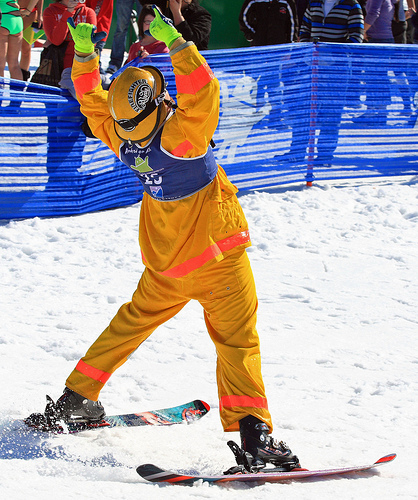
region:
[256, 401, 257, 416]
part of a skate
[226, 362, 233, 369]
back of a leg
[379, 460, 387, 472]
part of a skate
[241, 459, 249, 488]
edge of a skate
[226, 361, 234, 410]
part of a trouser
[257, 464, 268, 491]
edge of a board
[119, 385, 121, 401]
part of a board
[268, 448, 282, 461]
part of a skate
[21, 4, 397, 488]
person standing on skis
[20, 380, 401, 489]
pair of skis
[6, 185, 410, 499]
snow covered hill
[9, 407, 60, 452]
snow splash in air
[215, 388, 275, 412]
orange stripes on yellow outfit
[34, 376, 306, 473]
black snow shoes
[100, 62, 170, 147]
yellow helmet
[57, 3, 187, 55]
neon green gloves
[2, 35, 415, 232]
blue fabric fence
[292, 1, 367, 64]
striped sweater with zipper in front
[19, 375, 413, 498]
a pair of skis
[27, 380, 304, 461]
his boots are black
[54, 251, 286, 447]
his pants are yellow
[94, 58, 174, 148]
his helmet is yellow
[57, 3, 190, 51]
his gloves are neon green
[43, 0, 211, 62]
the gloves are green and blue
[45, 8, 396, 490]
he is dressed like a firefighter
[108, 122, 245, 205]
this is a blue vest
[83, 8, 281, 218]
the Android robot is on his vest and the fence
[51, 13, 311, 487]
there are orange reflective strips on his pants and jacket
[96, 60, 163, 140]
helmet on a skier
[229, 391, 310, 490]
snowboot on a skier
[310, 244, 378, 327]
white snow on the ground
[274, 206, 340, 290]
tracks in the snow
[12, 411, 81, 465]
snow spraying in the air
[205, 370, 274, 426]
orange reflective material on pants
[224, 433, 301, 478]
straps holding a boot to a ski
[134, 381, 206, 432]
decoration on a ski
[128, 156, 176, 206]
number on a vest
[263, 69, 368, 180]
blue barrier fence